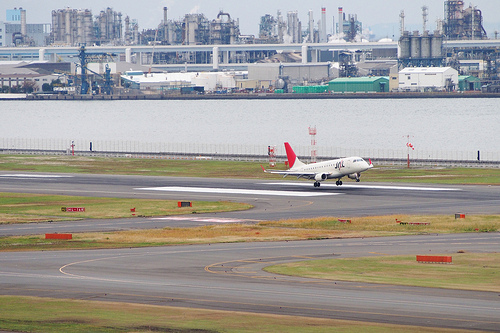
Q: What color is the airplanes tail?
A: Red.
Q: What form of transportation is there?
A: Airplane.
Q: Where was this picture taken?
A: Airport.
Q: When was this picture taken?
A: Daytime.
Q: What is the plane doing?
A: Taking off.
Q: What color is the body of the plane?
A: White.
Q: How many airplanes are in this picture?
A: 1.